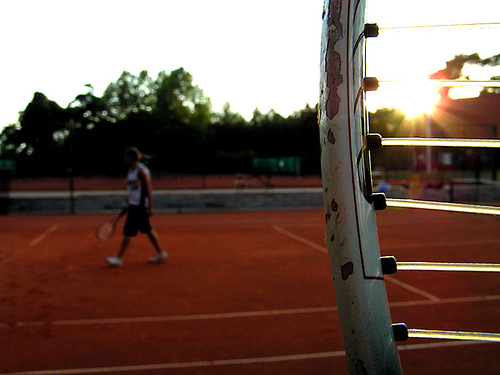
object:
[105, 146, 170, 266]
man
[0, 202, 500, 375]
tennis court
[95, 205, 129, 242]
tennis racket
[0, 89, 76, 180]
trees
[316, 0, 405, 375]
pole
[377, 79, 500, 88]
cables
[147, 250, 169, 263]
sneakers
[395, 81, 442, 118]
sun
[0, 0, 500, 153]
sky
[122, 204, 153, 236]
shorts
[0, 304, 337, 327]
white lines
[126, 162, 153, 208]
shirt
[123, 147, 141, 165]
head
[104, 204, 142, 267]
legs